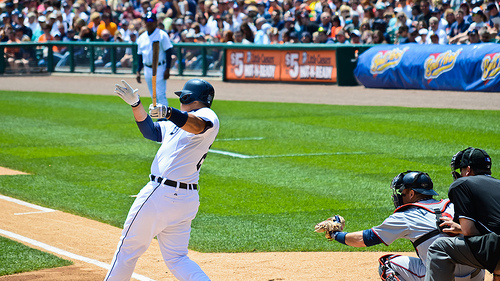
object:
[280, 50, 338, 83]
sign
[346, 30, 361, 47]
fans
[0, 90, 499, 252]
grass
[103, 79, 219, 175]
player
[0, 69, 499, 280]
field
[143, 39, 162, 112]
bat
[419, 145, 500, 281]
umpire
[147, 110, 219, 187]
shirt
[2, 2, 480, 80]
stands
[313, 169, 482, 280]
catcher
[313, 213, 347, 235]
ball